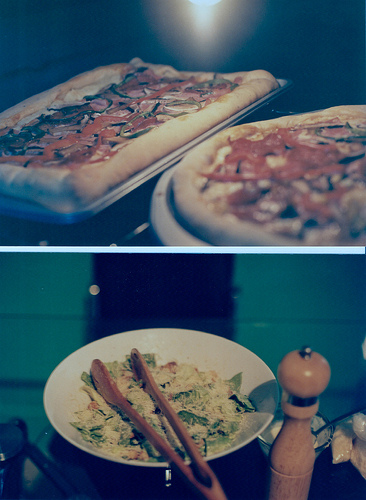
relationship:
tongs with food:
[93, 345, 222, 496] [79, 362, 273, 461]